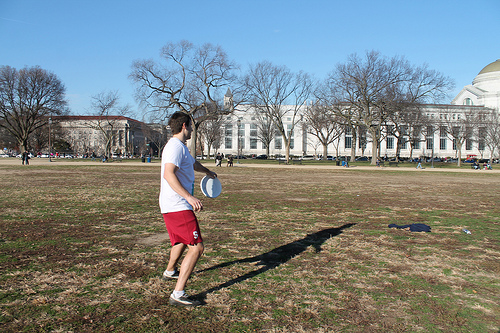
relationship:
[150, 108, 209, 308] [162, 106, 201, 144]
person has hair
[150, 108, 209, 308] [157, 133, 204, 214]
person wearing a shirt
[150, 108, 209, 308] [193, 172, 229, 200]
person holding frisbee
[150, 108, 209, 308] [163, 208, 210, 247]
person wearing shorts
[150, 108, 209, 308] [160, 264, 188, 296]
person wearing socks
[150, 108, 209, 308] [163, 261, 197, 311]
person wearing shoes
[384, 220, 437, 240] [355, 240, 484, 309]
clothing on grass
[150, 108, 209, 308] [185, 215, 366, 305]
person casting a shadow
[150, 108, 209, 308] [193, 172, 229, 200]
person throwing a frisbee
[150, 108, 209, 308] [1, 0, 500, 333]
person in a park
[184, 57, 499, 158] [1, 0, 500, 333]
building in park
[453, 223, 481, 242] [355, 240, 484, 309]
water bottle on grass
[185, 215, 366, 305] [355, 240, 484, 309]
shadow on grass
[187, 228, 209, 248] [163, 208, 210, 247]
s on shorts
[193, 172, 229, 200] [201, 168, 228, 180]
frisbee in hand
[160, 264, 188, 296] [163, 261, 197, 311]
socks are in shoes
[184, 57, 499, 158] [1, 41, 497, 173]
building behind trees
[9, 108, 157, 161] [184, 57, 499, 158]
small building next to building